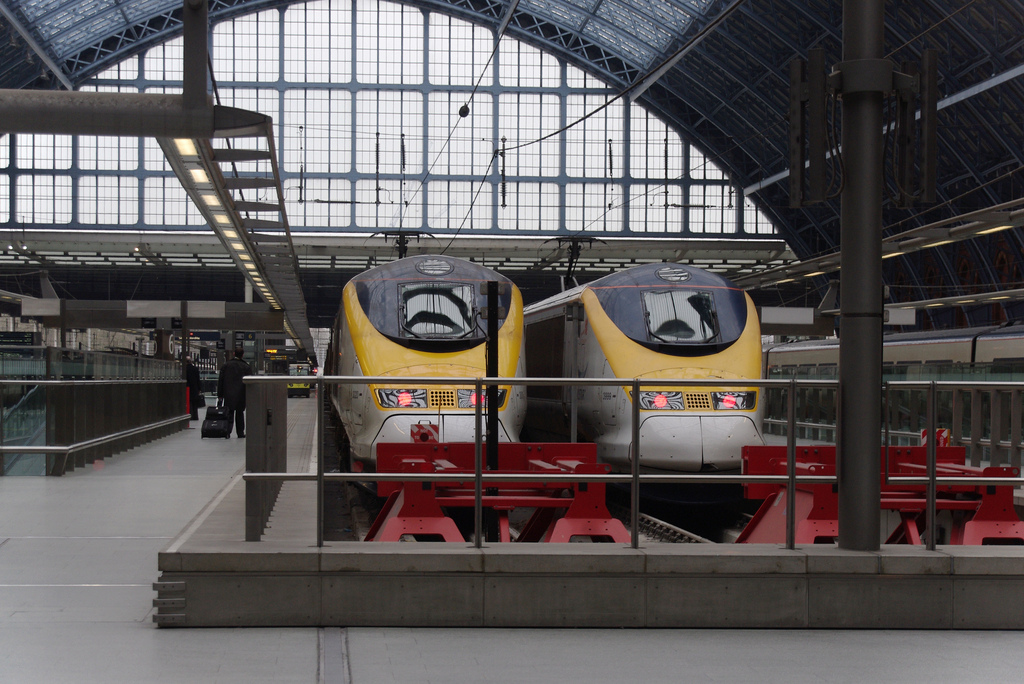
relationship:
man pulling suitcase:
[187, 345, 245, 428] [198, 398, 244, 428]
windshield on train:
[359, 271, 521, 345] [324, 252, 553, 540]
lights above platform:
[181, 136, 279, 321] [1, 370, 1017, 681]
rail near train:
[239, 375, 1023, 559] [328, 249, 526, 496]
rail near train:
[239, 375, 1023, 559] [527, 249, 756, 496]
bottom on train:
[601, 411, 772, 475] [524, 262, 771, 475]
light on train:
[716, 388, 759, 420] [516, 269, 779, 484]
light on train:
[636, 383, 688, 415] [516, 269, 779, 484]